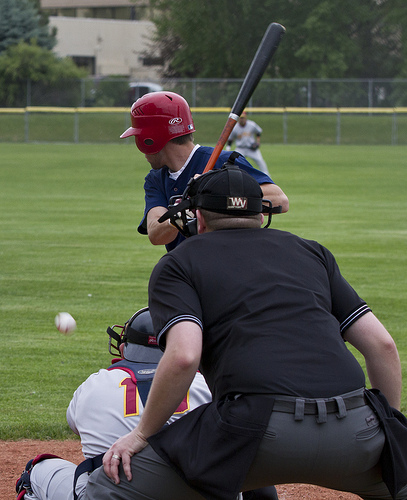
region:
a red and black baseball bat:
[187, 21, 282, 175]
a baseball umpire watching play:
[80, 167, 406, 486]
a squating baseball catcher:
[17, 308, 221, 498]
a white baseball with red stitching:
[55, 311, 77, 333]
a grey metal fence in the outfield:
[2, 79, 406, 151]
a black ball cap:
[196, 165, 262, 211]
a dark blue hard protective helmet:
[120, 308, 160, 364]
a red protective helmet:
[118, 88, 192, 149]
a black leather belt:
[272, 396, 367, 413]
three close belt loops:
[290, 398, 351, 422]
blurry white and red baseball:
[44, 307, 85, 333]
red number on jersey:
[116, 372, 197, 418]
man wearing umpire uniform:
[17, 301, 214, 498]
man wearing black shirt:
[101, 166, 397, 407]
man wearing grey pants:
[88, 156, 404, 498]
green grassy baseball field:
[8, 145, 137, 272]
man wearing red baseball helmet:
[113, 86, 213, 170]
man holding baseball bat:
[110, 14, 328, 241]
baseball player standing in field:
[229, 99, 279, 173]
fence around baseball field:
[262, 106, 405, 144]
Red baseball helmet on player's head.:
[118, 90, 195, 155]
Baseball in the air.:
[53, 310, 76, 335]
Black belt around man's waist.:
[270, 392, 365, 414]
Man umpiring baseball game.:
[80, 161, 406, 498]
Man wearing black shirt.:
[81, 165, 406, 498]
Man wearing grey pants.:
[80, 164, 405, 495]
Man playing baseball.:
[15, 305, 244, 498]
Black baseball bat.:
[200, 20, 286, 172]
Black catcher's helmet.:
[106, 303, 165, 363]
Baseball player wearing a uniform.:
[120, 90, 289, 254]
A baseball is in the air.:
[51, 309, 76, 335]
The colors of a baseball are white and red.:
[52, 308, 76, 339]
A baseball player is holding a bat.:
[115, 15, 290, 246]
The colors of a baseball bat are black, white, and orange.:
[170, 19, 286, 230]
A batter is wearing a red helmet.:
[118, 89, 197, 156]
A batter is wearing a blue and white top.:
[138, 142, 275, 256]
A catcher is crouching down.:
[14, 306, 237, 498]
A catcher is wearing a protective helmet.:
[103, 307, 174, 364]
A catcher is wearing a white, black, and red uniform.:
[16, 350, 214, 498]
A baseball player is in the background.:
[215, 106, 270, 178]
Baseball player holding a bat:
[118, 15, 293, 244]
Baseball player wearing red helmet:
[118, 88, 195, 156]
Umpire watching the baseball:
[71, 171, 405, 497]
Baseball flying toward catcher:
[53, 310, 77, 334]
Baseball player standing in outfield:
[225, 111, 269, 179]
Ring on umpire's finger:
[102, 429, 137, 484]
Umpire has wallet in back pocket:
[353, 428, 386, 472]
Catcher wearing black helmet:
[107, 304, 162, 364]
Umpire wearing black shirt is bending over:
[71, 169, 405, 496]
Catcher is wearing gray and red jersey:
[66, 300, 212, 459]